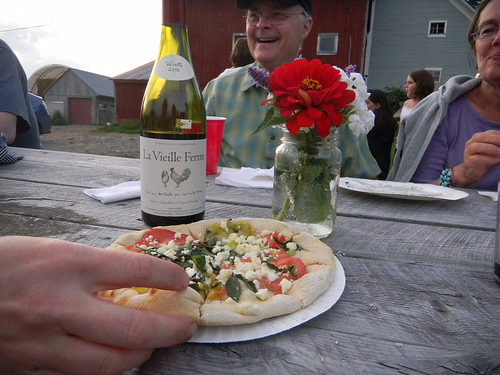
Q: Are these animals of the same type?
A: Yes, all the animals are chicken.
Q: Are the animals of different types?
A: No, all the animals are chicken.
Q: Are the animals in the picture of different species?
A: No, all the animals are chicken.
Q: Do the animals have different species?
A: No, all the animals are chicken.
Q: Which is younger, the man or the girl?
A: The girl is younger than the man.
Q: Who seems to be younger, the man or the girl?
A: The girl is younger than the man.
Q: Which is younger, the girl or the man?
A: The girl is younger than the man.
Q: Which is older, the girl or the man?
A: The man is older than the girl.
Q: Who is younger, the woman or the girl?
A: The girl is younger than the woman.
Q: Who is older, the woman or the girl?
A: The woman is older than the girl.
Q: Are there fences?
A: No, there are no fences.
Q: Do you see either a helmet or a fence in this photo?
A: No, there are no fences or helmets.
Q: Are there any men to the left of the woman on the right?
A: Yes, there is a man to the left of the woman.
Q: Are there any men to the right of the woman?
A: No, the man is to the left of the woman.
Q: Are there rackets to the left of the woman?
A: No, there is a man to the left of the woman.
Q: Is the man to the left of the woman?
A: Yes, the man is to the left of the woman.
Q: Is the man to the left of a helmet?
A: No, the man is to the left of the woman.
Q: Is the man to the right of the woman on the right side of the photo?
A: No, the man is to the left of the woman.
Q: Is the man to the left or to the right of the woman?
A: The man is to the left of the woman.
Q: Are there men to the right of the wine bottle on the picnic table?
A: Yes, there is a man to the right of the wine bottle.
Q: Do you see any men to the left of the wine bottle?
A: No, the man is to the right of the wine bottle.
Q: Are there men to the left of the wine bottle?
A: No, the man is to the right of the wine bottle.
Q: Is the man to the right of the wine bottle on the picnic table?
A: Yes, the man is to the right of the wine bottle.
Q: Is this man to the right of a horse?
A: No, the man is to the right of the wine bottle.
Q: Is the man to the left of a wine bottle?
A: No, the man is to the right of a wine bottle.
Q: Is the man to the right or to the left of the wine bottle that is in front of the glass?
A: The man is to the right of the wine bottle.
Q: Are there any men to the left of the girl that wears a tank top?
A: Yes, there is a man to the left of the girl.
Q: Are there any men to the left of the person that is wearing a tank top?
A: Yes, there is a man to the left of the girl.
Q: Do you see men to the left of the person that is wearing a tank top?
A: Yes, there is a man to the left of the girl.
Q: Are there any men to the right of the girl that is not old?
A: No, the man is to the left of the girl.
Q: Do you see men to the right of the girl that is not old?
A: No, the man is to the left of the girl.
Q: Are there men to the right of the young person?
A: No, the man is to the left of the girl.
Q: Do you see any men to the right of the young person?
A: No, the man is to the left of the girl.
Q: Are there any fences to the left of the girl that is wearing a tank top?
A: No, there is a man to the left of the girl.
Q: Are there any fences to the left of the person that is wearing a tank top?
A: No, there is a man to the left of the girl.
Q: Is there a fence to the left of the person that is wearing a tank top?
A: No, there is a man to the left of the girl.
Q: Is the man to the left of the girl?
A: Yes, the man is to the left of the girl.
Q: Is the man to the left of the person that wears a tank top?
A: Yes, the man is to the left of the girl.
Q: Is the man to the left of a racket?
A: No, the man is to the left of the girl.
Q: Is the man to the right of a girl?
A: No, the man is to the left of a girl.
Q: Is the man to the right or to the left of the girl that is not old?
A: The man is to the left of the girl.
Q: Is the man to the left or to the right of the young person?
A: The man is to the left of the girl.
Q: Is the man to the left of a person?
A: Yes, the man is to the left of a person.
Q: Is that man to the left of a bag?
A: No, the man is to the left of a person.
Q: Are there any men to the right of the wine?
A: Yes, there is a man to the right of the wine.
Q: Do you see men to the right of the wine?
A: Yes, there is a man to the right of the wine.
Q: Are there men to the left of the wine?
A: No, the man is to the right of the wine.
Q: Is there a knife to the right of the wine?
A: No, there is a man to the right of the wine.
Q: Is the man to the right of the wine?
A: Yes, the man is to the right of the wine.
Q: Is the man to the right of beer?
A: No, the man is to the right of the wine.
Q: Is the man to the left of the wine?
A: No, the man is to the right of the wine.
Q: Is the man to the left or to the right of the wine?
A: The man is to the right of the wine.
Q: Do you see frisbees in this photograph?
A: No, there are no frisbees.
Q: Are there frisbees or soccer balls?
A: No, there are no frisbees or soccer balls.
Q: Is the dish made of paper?
A: Yes, the dish is made of paper.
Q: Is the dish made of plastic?
A: No, the dish is made of paper.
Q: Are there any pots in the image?
A: No, there are no pots.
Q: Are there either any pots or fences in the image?
A: No, there are no pots or fences.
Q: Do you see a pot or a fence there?
A: No, there are no pots or fences.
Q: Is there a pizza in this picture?
A: Yes, there is a pizza.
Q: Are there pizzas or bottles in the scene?
A: Yes, there is a pizza.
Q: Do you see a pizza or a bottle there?
A: Yes, there is a pizza.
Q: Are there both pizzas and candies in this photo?
A: No, there is a pizza but no candies.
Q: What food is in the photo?
A: The food is a pizza.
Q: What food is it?
A: The food is a pizza.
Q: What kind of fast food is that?
A: This is a pizza.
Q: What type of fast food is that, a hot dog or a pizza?
A: This is a pizza.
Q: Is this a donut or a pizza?
A: This is a pizza.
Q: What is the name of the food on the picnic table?
A: The food is a pizza.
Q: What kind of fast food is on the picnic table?
A: The food is a pizza.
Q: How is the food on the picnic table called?
A: The food is a pizza.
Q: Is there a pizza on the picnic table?
A: Yes, there is a pizza on the picnic table.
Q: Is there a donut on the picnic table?
A: No, there is a pizza on the picnic table.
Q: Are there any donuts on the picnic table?
A: No, there is a pizza on the picnic table.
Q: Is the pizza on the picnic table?
A: Yes, the pizza is on the picnic table.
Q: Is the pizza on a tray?
A: No, the pizza is on the picnic table.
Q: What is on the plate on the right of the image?
A: The pizza is on the plate.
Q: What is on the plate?
A: The pizza is on the plate.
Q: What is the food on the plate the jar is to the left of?
A: The food is a pizza.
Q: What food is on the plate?
A: The food is a pizza.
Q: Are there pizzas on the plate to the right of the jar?
A: Yes, there is a pizza on the plate.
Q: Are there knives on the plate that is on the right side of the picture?
A: No, there is a pizza on the plate.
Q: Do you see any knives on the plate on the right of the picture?
A: No, there is a pizza on the plate.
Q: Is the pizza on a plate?
A: Yes, the pizza is on a plate.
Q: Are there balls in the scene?
A: No, there are no balls.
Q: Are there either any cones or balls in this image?
A: No, there are no balls or cones.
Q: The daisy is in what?
A: The daisy is in the jar.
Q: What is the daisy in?
A: The daisy is in the jar.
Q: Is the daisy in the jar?
A: Yes, the daisy is in the jar.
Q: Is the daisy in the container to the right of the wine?
A: Yes, the daisy is in the jar.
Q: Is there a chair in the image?
A: No, there are no chairs.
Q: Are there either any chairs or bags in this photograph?
A: No, there are no chairs or bags.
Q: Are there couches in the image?
A: No, there are no couches.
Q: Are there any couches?
A: No, there are no couches.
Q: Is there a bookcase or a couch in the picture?
A: No, there are no couches or bookcases.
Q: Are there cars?
A: No, there are no cars.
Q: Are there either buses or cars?
A: No, there are no cars or buses.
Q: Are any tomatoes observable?
A: Yes, there is a tomato.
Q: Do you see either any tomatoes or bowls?
A: Yes, there is a tomato.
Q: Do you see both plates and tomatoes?
A: Yes, there are both a tomato and a plate.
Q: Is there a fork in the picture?
A: No, there are no forks.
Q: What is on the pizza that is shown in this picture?
A: The tomato is on the pizza.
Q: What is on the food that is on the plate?
A: The tomato is on the pizza.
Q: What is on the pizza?
A: The tomato is on the pizza.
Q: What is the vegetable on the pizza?
A: The vegetable is a tomato.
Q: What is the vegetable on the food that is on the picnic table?
A: The vegetable is a tomato.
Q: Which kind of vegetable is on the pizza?
A: The vegetable is a tomato.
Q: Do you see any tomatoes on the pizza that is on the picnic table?
A: Yes, there is a tomato on the pizza.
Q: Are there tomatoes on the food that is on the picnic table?
A: Yes, there is a tomato on the pizza.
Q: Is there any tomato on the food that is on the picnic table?
A: Yes, there is a tomato on the pizza.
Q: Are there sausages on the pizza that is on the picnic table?
A: No, there is a tomato on the pizza.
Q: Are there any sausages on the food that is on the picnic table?
A: No, there is a tomato on the pizza.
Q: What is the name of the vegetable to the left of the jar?
A: The vegetable is a tomato.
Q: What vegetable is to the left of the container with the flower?
A: The vegetable is a tomato.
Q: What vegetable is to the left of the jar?
A: The vegetable is a tomato.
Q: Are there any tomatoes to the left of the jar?
A: Yes, there is a tomato to the left of the jar.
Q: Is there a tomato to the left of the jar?
A: Yes, there is a tomato to the left of the jar.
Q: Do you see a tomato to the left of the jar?
A: Yes, there is a tomato to the left of the jar.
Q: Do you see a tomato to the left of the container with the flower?
A: Yes, there is a tomato to the left of the jar.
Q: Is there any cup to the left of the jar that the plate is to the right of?
A: No, there is a tomato to the left of the jar.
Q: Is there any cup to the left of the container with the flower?
A: No, there is a tomato to the left of the jar.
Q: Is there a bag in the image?
A: No, there are no bags.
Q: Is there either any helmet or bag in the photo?
A: No, there are no bags or helmets.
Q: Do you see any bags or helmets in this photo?
A: No, there are no bags or helmets.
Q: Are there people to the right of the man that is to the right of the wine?
A: Yes, there is a person to the right of the man.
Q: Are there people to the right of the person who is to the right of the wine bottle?
A: Yes, there is a person to the right of the man.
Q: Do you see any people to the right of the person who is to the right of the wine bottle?
A: Yes, there is a person to the right of the man.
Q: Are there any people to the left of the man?
A: No, the person is to the right of the man.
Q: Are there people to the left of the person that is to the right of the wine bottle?
A: No, the person is to the right of the man.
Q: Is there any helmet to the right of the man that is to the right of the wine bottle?
A: No, there is a person to the right of the man.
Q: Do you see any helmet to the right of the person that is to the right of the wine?
A: No, there is a person to the right of the man.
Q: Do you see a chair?
A: No, there are no chairs.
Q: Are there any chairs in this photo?
A: No, there are no chairs.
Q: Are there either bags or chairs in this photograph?
A: No, there are no chairs or bags.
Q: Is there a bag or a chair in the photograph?
A: No, there are no chairs or bags.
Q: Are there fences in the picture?
A: No, there are no fences.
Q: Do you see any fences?
A: No, there are no fences.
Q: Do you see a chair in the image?
A: No, there are no chairs.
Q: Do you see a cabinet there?
A: No, there are no cabinets.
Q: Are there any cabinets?
A: No, there are no cabinets.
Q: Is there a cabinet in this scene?
A: No, there are no cabinets.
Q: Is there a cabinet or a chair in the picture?
A: No, there are no cabinets or chairs.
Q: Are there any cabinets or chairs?
A: No, there are no cabinets or chairs.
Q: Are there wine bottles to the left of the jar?
A: Yes, there is a wine bottle to the left of the jar.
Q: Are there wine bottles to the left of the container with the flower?
A: Yes, there is a wine bottle to the left of the jar.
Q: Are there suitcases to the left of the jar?
A: No, there is a wine bottle to the left of the jar.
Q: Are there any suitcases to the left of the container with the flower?
A: No, there is a wine bottle to the left of the jar.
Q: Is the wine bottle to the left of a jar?
A: Yes, the wine bottle is to the left of a jar.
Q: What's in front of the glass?
A: The wine bottle is in front of the glass.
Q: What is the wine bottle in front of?
A: The wine bottle is in front of the glass.